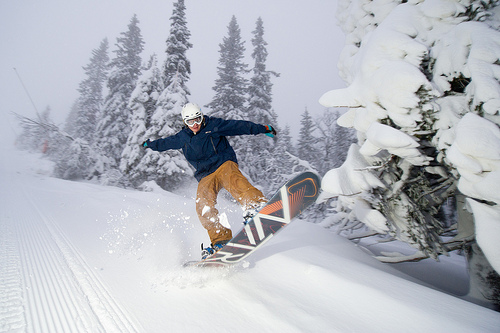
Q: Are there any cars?
A: No, there are no cars.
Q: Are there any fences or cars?
A: No, there are no cars or fences.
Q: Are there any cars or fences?
A: No, there are no cars or fences.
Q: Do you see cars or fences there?
A: No, there are no cars or fences.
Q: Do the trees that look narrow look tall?
A: Yes, the trees are tall.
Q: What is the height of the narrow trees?
A: The trees are tall.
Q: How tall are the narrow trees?
A: The trees are tall.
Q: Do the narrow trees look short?
A: No, the trees are tall.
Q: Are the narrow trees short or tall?
A: The trees are tall.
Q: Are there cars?
A: No, there are no cars.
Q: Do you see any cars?
A: No, there are no cars.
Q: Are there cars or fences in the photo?
A: No, there are no cars or fences.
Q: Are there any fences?
A: No, there are no fences.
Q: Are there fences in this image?
A: No, there are no fences.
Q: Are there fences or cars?
A: No, there are no fences or cars.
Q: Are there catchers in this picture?
A: No, there are no catchers.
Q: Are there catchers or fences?
A: No, there are no catchers or fences.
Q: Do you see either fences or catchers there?
A: No, there are no catchers or fences.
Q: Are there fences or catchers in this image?
A: No, there are no catchers or fences.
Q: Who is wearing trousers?
A: The man is wearing trousers.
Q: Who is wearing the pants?
A: The man is wearing trousers.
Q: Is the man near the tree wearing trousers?
A: Yes, the man is wearing trousers.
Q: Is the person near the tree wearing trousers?
A: Yes, the man is wearing trousers.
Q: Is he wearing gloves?
A: No, the man is wearing trousers.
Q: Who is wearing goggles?
A: The man is wearing goggles.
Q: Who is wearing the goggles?
A: The man is wearing goggles.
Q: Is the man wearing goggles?
A: Yes, the man is wearing goggles.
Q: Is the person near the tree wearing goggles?
A: Yes, the man is wearing goggles.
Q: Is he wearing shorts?
A: No, the man is wearing goggles.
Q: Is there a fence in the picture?
A: No, there are no fences.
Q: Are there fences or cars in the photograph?
A: No, there are no fences or cars.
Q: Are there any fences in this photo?
A: No, there are no fences.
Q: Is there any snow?
A: Yes, there is snow.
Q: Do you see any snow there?
A: Yes, there is snow.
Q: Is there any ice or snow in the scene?
A: Yes, there is snow.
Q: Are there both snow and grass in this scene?
A: No, there is snow but no grass.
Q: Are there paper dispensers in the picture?
A: No, there are no paper dispensers.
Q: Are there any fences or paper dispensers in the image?
A: No, there are no paper dispensers or fences.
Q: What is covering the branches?
A: The snow is covering the branches.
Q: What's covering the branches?
A: The snow is covering the branches.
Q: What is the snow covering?
A: The snow is covering the branches.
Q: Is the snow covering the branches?
A: Yes, the snow is covering the branches.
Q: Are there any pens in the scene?
A: No, there are no pens.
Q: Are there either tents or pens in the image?
A: No, there are no pens or tents.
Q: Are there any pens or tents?
A: No, there are no pens or tents.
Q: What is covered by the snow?
A: The branches are covered by the snow.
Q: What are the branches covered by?
A: The branches are covered by the snow.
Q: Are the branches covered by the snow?
A: Yes, the branches are covered by the snow.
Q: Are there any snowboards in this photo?
A: Yes, there is a snowboard.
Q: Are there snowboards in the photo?
A: Yes, there is a snowboard.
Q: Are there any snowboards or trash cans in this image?
A: Yes, there is a snowboard.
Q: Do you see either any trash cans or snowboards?
A: Yes, there is a snowboard.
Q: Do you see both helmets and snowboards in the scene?
A: Yes, there are both a snowboard and a helmet.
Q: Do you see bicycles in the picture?
A: No, there are no bicycles.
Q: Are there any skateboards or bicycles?
A: No, there are no bicycles or skateboards.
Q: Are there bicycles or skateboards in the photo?
A: No, there are no bicycles or skateboards.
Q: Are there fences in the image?
A: No, there are no fences.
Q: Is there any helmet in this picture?
A: Yes, there is a helmet.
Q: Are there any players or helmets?
A: Yes, there is a helmet.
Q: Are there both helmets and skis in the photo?
A: No, there is a helmet but no skis.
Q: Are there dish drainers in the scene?
A: No, there are no dish drainers.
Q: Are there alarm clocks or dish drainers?
A: No, there are no dish drainers or alarm clocks.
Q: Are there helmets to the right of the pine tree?
A: Yes, there is a helmet to the right of the pine tree.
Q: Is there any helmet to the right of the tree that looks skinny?
A: Yes, there is a helmet to the right of the pine tree.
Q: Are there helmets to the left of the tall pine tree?
A: No, the helmet is to the right of the pine tree.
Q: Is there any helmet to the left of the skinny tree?
A: No, the helmet is to the right of the pine tree.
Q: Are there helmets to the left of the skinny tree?
A: No, the helmet is to the right of the pine tree.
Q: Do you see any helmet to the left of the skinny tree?
A: No, the helmet is to the right of the pine tree.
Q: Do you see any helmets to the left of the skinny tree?
A: No, the helmet is to the right of the pine tree.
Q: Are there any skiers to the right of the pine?
A: No, there is a helmet to the right of the pine.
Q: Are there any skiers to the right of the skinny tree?
A: No, there is a helmet to the right of the pine.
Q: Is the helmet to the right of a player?
A: No, the helmet is to the right of the pine tree.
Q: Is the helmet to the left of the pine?
A: No, the helmet is to the right of the pine.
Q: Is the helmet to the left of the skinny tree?
A: No, the helmet is to the right of the pine.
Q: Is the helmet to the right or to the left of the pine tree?
A: The helmet is to the right of the pine tree.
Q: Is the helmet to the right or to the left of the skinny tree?
A: The helmet is to the right of the pine tree.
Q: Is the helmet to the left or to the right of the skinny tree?
A: The helmet is to the right of the pine tree.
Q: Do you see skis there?
A: No, there are no skis.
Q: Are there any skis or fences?
A: No, there are no skis or fences.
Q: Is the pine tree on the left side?
A: Yes, the pine tree is on the left of the image.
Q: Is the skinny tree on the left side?
A: Yes, the pine tree is on the left of the image.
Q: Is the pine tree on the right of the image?
A: No, the pine tree is on the left of the image.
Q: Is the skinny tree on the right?
A: No, the pine tree is on the left of the image.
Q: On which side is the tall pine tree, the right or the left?
A: The pine is on the left of the image.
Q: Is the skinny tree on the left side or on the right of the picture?
A: The pine is on the left of the image.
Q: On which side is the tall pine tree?
A: The pine tree is on the left of the image.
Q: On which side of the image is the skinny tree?
A: The pine tree is on the left of the image.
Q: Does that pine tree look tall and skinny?
A: Yes, the pine tree is tall and skinny.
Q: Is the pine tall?
A: Yes, the pine is tall.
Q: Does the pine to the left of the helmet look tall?
A: Yes, the pine is tall.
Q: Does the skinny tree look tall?
A: Yes, the pine is tall.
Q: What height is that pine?
A: The pine is tall.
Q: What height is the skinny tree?
A: The pine is tall.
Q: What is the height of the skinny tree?
A: The pine is tall.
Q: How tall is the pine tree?
A: The pine tree is tall.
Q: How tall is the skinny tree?
A: The pine tree is tall.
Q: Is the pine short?
A: No, the pine is tall.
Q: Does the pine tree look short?
A: No, the pine tree is tall.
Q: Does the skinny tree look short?
A: No, the pine tree is tall.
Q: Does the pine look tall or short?
A: The pine is tall.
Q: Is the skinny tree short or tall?
A: The pine is tall.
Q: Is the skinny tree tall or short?
A: The pine is tall.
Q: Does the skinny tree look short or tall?
A: The pine is tall.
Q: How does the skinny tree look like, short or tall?
A: The pine is tall.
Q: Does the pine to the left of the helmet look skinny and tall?
A: Yes, the pine is skinny and tall.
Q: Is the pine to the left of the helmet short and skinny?
A: No, the pine is skinny but tall.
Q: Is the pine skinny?
A: Yes, the pine is skinny.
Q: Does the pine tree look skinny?
A: Yes, the pine tree is skinny.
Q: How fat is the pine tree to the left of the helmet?
A: The pine is skinny.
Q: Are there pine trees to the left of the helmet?
A: Yes, there is a pine tree to the left of the helmet.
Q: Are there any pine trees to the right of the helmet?
A: No, the pine tree is to the left of the helmet.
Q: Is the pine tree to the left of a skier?
A: No, the pine tree is to the left of the helmet.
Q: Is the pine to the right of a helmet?
A: No, the pine is to the left of a helmet.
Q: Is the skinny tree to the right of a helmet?
A: No, the pine is to the left of a helmet.